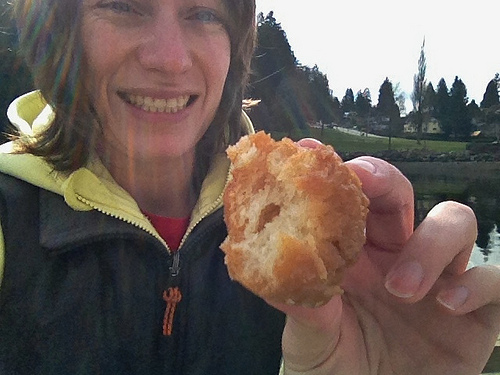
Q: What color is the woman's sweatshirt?
A: Yellow.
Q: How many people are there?
A: 1.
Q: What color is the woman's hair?
A: Brown.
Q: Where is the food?
A: In the woman's hand.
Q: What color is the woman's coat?
A: Black.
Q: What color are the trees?
A: Green.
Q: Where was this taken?
A: By the water.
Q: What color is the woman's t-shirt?
A: Red.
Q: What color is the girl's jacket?
A: Black.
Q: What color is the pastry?
A: Brown.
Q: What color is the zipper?
A: Orange.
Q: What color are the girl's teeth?
A: Yellow.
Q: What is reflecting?
A: The water.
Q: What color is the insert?
A: Yellow.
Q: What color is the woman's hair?
A: Brown.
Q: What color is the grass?
A: Green.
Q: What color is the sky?
A: White.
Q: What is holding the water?
A: A lake.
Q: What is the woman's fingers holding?
A: A donut.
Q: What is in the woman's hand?
A: A donut.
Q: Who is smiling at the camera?
A: A woman.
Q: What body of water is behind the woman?
A: A lake.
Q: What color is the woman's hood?
A: Yellow.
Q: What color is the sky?
A: Clear, white.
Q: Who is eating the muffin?
A: The woman.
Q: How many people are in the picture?
A: One.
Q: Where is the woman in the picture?
A: In front of the pond.